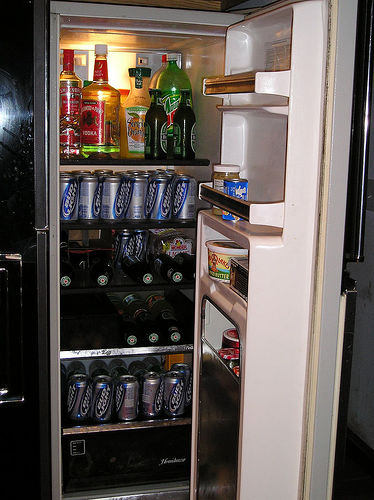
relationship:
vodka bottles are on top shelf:
[58, 35, 119, 168] [64, 28, 221, 176]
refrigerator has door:
[6, 3, 372, 487] [185, 2, 372, 492]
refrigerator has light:
[6, 3, 372, 487] [73, 30, 138, 91]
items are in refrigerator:
[57, 27, 249, 422] [6, 3, 372, 487]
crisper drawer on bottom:
[44, 415, 199, 492] [43, 422, 302, 495]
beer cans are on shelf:
[61, 165, 202, 228] [64, 171, 219, 240]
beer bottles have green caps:
[55, 248, 194, 292] [58, 273, 185, 286]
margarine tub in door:
[199, 233, 249, 291] [185, 2, 372, 492]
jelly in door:
[211, 344, 252, 387] [185, 2, 372, 492]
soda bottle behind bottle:
[147, 50, 195, 165] [171, 85, 204, 163]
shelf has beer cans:
[64, 171, 219, 240] [61, 165, 202, 228]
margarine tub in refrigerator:
[199, 233, 249, 291] [6, 3, 372, 487]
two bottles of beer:
[141, 77, 199, 174] [141, 107, 194, 149]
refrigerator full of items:
[6, 3, 372, 487] [57, 27, 249, 422]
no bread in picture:
[37, 63, 217, 104] [191, 70, 330, 120]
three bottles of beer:
[51, 245, 161, 290] [141, 107, 194, 149]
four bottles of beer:
[61, 244, 188, 292] [141, 107, 194, 149]